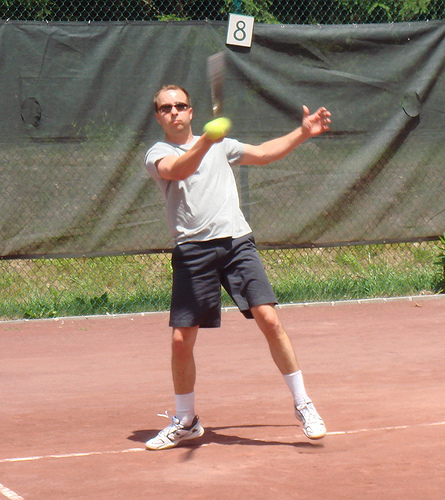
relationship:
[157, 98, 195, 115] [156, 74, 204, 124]
sunglasses on face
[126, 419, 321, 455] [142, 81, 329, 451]
shadow of he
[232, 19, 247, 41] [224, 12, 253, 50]
number 8 written on card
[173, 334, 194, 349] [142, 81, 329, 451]
knee belonging to he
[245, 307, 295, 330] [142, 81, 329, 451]
knee belonging to he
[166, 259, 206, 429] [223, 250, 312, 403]
leg separated from leg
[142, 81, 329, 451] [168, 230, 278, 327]
he wearing shorts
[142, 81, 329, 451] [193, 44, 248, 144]
he swinging a racket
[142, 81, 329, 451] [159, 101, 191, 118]
he wearing goggles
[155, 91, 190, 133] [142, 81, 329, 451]
face of he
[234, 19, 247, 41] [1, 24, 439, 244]
number 8 on fence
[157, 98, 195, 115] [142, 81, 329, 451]
sunglasses on he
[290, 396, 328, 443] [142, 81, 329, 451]
shoe on he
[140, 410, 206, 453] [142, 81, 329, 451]
shoe on he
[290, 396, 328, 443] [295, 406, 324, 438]
shoe on foot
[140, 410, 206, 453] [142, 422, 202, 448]
shoe on foot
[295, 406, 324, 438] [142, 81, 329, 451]
foot of he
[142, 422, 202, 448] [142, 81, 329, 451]
foot of he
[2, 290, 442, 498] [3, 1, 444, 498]
chalk on court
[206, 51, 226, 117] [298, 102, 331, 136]
racket in hand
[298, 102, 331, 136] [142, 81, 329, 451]
hand of he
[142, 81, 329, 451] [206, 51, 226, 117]
he holding racket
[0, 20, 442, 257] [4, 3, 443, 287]
tarp on fence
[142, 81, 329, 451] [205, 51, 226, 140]
he swinging racket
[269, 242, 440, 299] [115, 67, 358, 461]
grass behind man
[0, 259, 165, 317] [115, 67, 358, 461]
grass behind man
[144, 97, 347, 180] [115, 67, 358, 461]
arms of man